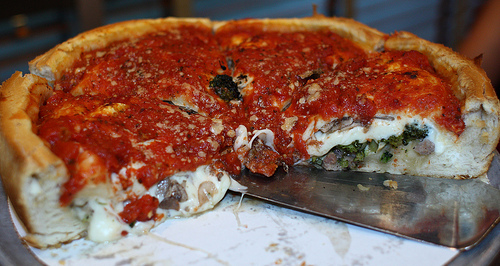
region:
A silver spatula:
[222, 147, 493, 262]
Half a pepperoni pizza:
[2, 7, 494, 199]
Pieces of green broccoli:
[334, 145, 416, 160]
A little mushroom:
[184, 173, 224, 212]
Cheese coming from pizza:
[88, 202, 127, 244]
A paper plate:
[173, 217, 369, 263]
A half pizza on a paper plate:
[4, 2, 494, 264]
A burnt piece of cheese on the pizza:
[212, 72, 239, 100]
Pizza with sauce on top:
[8, 15, 495, 182]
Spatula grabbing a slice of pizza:
[219, 133, 498, 250]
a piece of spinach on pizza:
[173, 48, 278, 119]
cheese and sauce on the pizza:
[66, 179, 211, 249]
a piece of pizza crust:
[382, 18, 474, 73]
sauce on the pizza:
[84, 63, 184, 143]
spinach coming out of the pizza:
[321, 127, 443, 182]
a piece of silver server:
[288, 172, 498, 209]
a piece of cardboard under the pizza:
[194, 221, 311, 264]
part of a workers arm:
[439, 2, 499, 95]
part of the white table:
[0, 207, 30, 264]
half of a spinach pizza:
[5, 7, 242, 256]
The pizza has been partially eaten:
[17, 22, 487, 239]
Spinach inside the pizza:
[315, 145, 435, 165]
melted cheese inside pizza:
[120, 157, 218, 205]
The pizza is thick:
[19, 95, 219, 254]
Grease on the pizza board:
[245, 211, 308, 262]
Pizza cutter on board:
[269, 135, 480, 244]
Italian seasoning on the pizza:
[112, 45, 219, 129]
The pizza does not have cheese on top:
[62, 52, 142, 140]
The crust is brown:
[8, 71, 77, 257]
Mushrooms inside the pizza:
[145, 158, 238, 218]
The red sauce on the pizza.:
[42, 35, 442, 150]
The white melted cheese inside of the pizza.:
[68, 117, 415, 212]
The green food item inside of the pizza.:
[305, 120, 438, 165]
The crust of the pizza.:
[7, 27, 487, 217]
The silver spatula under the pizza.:
[253, 161, 496, 255]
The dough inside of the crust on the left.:
[29, 172, 79, 232]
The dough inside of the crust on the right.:
[450, 109, 482, 176]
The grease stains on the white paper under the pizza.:
[42, 236, 424, 265]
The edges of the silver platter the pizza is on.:
[4, 212, 493, 264]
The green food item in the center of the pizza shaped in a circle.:
[204, 65, 250, 104]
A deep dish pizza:
[4, 24, 499, 234]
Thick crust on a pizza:
[3, 65, 88, 235]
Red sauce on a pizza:
[51, 81, 208, 176]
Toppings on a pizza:
[77, 41, 437, 177]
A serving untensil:
[248, 139, 498, 248]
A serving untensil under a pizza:
[216, 134, 499, 244]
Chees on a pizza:
[287, 99, 472, 163]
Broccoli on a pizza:
[319, 118, 456, 168]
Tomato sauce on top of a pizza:
[8, 23, 498, 184]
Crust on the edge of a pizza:
[26, 10, 476, 66]